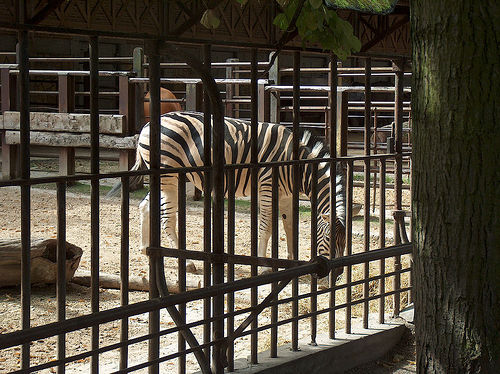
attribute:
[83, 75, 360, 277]
zebra — black, white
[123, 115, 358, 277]
zebra — black, white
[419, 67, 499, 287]
log — large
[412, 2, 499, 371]
treebark — grey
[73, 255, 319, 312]
log — wooden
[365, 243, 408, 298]
grass — short, dried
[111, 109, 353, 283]
zebra — grazing, stripes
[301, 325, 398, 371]
curb — cement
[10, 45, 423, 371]
cage — wire rods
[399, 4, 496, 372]
tree trunk — large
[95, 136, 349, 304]
zebra — grazing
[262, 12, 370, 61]
leaves — green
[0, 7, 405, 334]
bars — black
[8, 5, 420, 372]
bars — grey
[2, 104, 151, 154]
slats — large , wooden 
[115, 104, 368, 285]
zebra — eating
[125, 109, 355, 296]
zebra — black , white